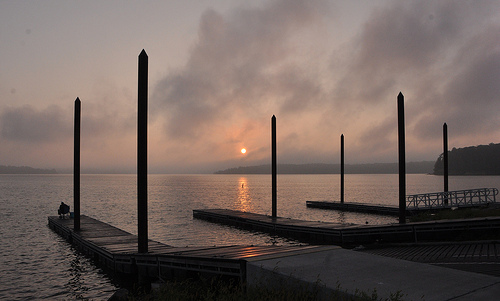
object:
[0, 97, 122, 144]
cloud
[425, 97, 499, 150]
ground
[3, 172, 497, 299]
water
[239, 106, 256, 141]
wall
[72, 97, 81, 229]
wood post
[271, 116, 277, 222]
wood post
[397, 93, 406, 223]
wood post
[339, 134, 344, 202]
wood post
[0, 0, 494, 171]
blue sky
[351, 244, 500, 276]
walkway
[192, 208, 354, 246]
boat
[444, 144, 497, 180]
trees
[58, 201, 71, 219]
person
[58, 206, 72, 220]
chair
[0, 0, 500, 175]
sky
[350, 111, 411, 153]
clouds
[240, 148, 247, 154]
sun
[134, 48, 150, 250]
pole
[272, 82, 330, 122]
clouds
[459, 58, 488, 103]
clouds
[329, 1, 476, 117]
clouds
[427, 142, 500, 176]
hill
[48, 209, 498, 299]
dock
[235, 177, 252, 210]
sun reflection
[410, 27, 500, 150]
clouds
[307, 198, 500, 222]
dock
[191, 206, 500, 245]
boat dock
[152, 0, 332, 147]
clouds